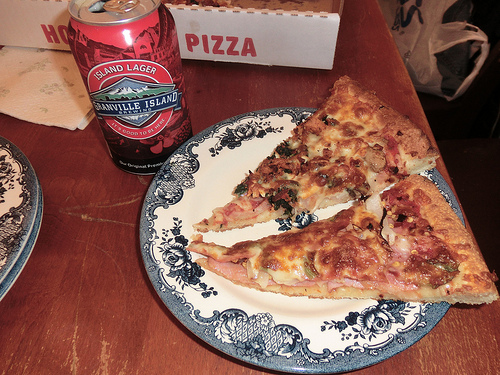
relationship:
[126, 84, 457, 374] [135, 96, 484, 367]
plate with edges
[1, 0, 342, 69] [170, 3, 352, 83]
cardboard of pizza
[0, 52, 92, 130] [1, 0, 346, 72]
napkins under cardboard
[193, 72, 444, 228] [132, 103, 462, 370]
pizza on plate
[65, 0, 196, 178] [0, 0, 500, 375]
lager on wooden table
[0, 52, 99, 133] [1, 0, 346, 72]
napkins under cardboard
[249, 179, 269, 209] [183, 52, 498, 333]
ham on pizza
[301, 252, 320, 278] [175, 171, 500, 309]
pepper on pizza slice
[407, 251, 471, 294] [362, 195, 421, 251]
onion on pizza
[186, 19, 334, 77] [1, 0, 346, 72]
red lettering on cardboard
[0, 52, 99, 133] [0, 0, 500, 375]
napkins on wooden table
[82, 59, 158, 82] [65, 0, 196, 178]
lettering on lager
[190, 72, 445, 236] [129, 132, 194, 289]
pizza on plate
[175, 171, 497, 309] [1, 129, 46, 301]
pizza slice on plate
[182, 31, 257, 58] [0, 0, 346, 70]
word on box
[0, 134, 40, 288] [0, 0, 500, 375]
plate on wooden table